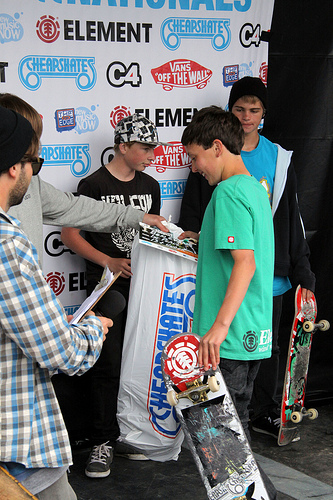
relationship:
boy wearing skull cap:
[180, 69, 315, 396] [228, 76, 268, 113]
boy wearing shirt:
[178, 76, 319, 442] [181, 136, 314, 288]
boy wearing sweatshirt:
[178, 76, 319, 442] [179, 139, 319, 295]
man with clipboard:
[1, 105, 111, 498] [65, 261, 123, 324]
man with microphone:
[1, 105, 111, 498] [92, 289, 127, 318]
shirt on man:
[1, 205, 98, 475] [1, 105, 111, 498]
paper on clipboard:
[64, 268, 117, 324] [63, 261, 128, 326]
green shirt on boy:
[196, 173, 274, 360] [186, 104, 275, 498]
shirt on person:
[238, 131, 280, 199] [181, 105, 274, 339]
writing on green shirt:
[239, 326, 274, 353] [191, 173, 276, 362]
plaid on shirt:
[9, 236, 40, 333] [8, 229, 103, 470]